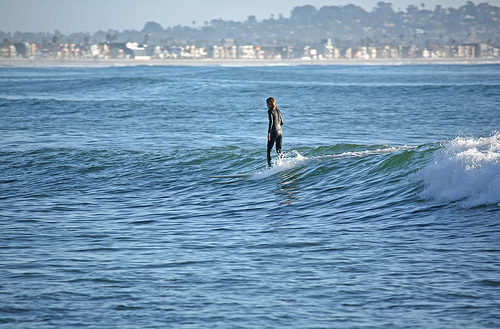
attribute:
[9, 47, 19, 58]
building — small, here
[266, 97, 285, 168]
woman — surfing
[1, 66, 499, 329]
water — white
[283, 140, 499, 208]
wave — small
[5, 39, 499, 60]
city — distant, here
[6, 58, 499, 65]
shore — distant